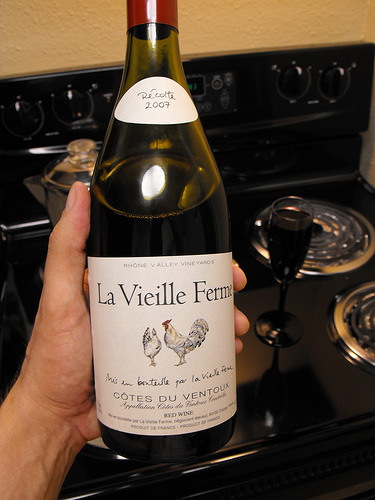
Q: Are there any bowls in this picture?
A: No, there are no bowls.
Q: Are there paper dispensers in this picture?
A: No, there are no paper dispensers.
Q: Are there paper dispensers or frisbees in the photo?
A: No, there are no paper dispensers or frisbees.